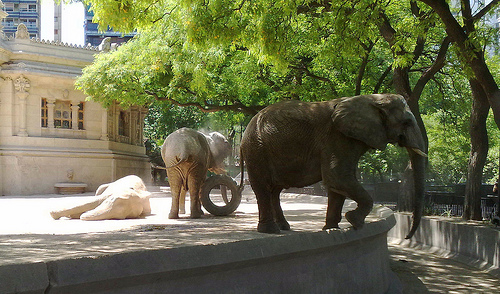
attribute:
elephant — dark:
[237, 85, 430, 249]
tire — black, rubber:
[194, 160, 259, 229]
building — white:
[2, 5, 174, 189]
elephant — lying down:
[49, 172, 151, 219]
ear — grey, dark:
[324, 90, 394, 155]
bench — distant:
[2, 52, 169, 207]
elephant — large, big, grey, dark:
[236, 90, 428, 237]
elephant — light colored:
[48, 162, 156, 237]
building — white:
[0, 27, 158, 196]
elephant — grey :
[142, 114, 266, 231]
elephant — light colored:
[52, 177, 157, 227]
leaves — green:
[85, 2, 473, 164]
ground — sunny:
[13, 192, 499, 282]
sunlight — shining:
[0, 173, 255, 241]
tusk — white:
[410, 147, 433, 162]